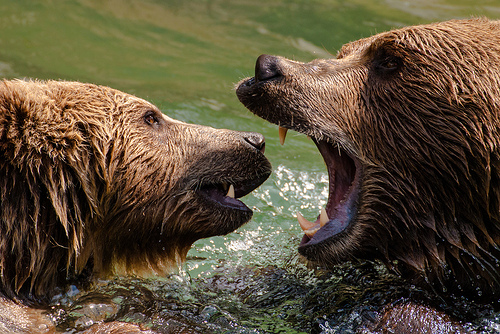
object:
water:
[208, 275, 281, 310]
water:
[185, 261, 257, 302]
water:
[237, 269, 299, 308]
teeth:
[278, 125, 287, 145]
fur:
[406, 112, 447, 191]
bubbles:
[223, 262, 265, 302]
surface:
[203, 258, 312, 323]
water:
[3, 0, 248, 108]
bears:
[54, 49, 482, 295]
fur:
[16, 87, 76, 187]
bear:
[258, 51, 483, 310]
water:
[68, 220, 331, 327]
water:
[60, 28, 254, 111]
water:
[106, 6, 247, 133]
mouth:
[255, 120, 380, 300]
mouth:
[167, 129, 257, 208]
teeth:
[272, 210, 364, 277]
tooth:
[222, 182, 228, 190]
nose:
[245, 46, 306, 76]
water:
[73, 16, 293, 144]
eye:
[348, 16, 469, 127]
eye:
[128, 110, 178, 142]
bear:
[1, 65, 278, 326]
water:
[1, 1, 498, 332]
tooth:
[296, 212, 316, 239]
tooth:
[318, 207, 331, 228]